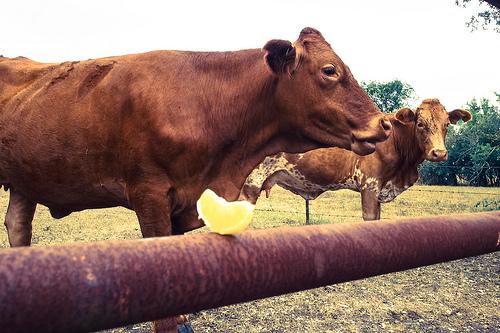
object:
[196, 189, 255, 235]
orange slice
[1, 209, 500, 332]
pole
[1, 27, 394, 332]
cow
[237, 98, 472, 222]
cow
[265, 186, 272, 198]
nipple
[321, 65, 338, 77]
eye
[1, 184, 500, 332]
grass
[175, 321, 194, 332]
hoof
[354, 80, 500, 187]
trees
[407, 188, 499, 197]
barbed wire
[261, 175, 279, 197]
udders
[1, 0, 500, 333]
field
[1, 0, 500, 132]
sky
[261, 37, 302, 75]
ear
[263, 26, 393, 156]
head